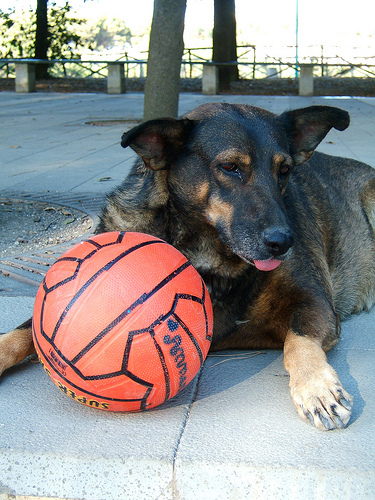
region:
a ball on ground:
[30, 224, 217, 416]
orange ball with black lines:
[29, 226, 216, 415]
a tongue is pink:
[249, 259, 285, 272]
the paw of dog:
[285, 375, 357, 429]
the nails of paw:
[303, 392, 353, 431]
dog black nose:
[262, 229, 295, 258]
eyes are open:
[213, 158, 297, 178]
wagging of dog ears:
[120, 103, 351, 168]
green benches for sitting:
[0, 55, 374, 96]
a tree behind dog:
[141, 0, 189, 118]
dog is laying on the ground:
[20, 96, 369, 380]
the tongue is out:
[233, 244, 294, 284]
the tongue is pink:
[237, 250, 297, 271]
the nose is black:
[248, 207, 306, 250]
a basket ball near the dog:
[24, 197, 230, 449]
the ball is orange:
[18, 200, 229, 414]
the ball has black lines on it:
[19, 210, 218, 417]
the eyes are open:
[194, 140, 307, 193]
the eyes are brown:
[189, 144, 302, 190]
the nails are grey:
[290, 394, 360, 441]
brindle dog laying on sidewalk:
[0, 98, 373, 481]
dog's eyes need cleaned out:
[133, 113, 329, 286]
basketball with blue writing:
[17, 231, 248, 416]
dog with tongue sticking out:
[102, 93, 353, 294]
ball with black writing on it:
[17, 225, 226, 445]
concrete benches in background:
[5, 36, 374, 120]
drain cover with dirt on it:
[1, 173, 109, 297]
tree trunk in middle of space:
[129, 0, 192, 116]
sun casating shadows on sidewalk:
[90, 339, 292, 427]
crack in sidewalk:
[151, 377, 214, 488]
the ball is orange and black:
[24, 221, 220, 431]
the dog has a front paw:
[278, 367, 358, 445]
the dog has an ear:
[275, 92, 351, 160]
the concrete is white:
[215, 401, 261, 450]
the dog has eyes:
[206, 142, 304, 196]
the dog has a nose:
[261, 221, 297, 255]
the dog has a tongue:
[241, 251, 287, 274]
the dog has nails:
[296, 391, 361, 439]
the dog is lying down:
[0, 87, 373, 430]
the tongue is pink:
[252, 254, 283, 274]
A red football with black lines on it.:
[30, 227, 213, 415]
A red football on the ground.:
[30, 225, 212, 412]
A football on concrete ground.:
[27, 226, 211, 407]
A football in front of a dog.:
[27, 226, 212, 408]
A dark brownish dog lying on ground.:
[1, 95, 369, 428]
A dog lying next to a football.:
[4, 97, 366, 429]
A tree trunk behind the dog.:
[139, 0, 180, 114]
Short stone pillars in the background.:
[0, 53, 360, 90]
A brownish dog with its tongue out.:
[0, 99, 370, 429]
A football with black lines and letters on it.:
[32, 229, 219, 415]